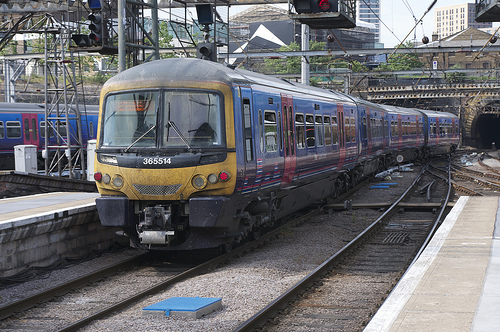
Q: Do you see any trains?
A: Yes, there is a train.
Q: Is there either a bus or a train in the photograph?
A: Yes, there is a train.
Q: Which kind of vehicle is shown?
A: The vehicle is a train.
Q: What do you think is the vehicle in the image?
A: The vehicle is a train.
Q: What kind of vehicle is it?
A: The vehicle is a train.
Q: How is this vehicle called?
A: This is a train.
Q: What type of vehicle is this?
A: This is a train.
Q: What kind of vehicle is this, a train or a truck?
A: This is a train.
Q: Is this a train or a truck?
A: This is a train.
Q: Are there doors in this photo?
A: Yes, there is a door.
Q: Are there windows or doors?
A: Yes, there is a door.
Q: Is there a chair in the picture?
A: No, there are no chairs.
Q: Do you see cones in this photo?
A: No, there are no cones.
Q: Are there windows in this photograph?
A: Yes, there are windows.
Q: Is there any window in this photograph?
A: Yes, there are windows.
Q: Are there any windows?
A: Yes, there are windows.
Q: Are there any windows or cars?
A: Yes, there are windows.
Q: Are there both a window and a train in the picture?
A: Yes, there are both a window and a train.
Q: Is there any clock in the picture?
A: No, there are no clocks.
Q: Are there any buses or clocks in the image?
A: No, there are no clocks or buses.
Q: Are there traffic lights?
A: Yes, there is a traffic light.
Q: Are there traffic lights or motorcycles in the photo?
A: Yes, there is a traffic light.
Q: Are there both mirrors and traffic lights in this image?
A: No, there is a traffic light but no mirrors.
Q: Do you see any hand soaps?
A: No, there are no hand soaps.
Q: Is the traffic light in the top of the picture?
A: Yes, the traffic light is in the top of the image.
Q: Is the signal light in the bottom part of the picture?
A: No, the signal light is in the top of the image.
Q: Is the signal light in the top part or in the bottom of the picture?
A: The signal light is in the top of the image.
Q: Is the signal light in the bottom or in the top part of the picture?
A: The signal light is in the top of the image.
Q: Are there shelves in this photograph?
A: No, there are no shelves.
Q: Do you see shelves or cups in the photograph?
A: No, there are no shelves or cups.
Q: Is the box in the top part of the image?
A: No, the box is in the bottom of the image.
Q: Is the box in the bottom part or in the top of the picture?
A: The box is in the bottom of the image.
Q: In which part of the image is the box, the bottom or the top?
A: The box is in the bottom of the image.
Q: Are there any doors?
A: Yes, there are doors.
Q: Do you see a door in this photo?
A: Yes, there are doors.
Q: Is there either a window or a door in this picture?
A: Yes, there are doors.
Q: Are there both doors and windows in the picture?
A: Yes, there are both doors and a window.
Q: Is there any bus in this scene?
A: No, there are no buses.